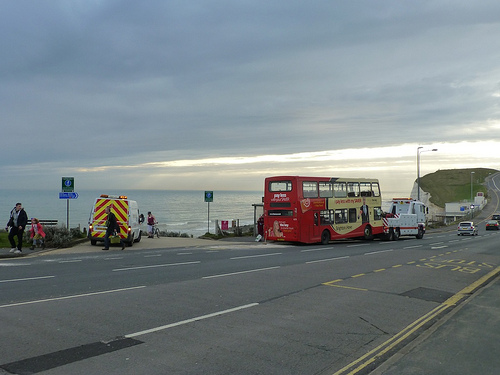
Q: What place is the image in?
A: It is at the road.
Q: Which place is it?
A: It is a road.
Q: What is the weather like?
A: It is cloudy.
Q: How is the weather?
A: It is cloudy.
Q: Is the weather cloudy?
A: Yes, it is cloudy.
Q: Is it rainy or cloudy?
A: It is cloudy.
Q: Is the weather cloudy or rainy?
A: It is cloudy.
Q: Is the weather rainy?
A: No, it is cloudy.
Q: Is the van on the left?
A: Yes, the van is on the left of the image.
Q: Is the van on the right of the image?
A: No, the van is on the left of the image.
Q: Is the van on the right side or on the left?
A: The van is on the left of the image.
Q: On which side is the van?
A: The van is on the left of the image.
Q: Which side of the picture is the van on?
A: The van is on the left of the image.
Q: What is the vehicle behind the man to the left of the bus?
A: The vehicle is a van.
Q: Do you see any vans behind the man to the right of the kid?
A: Yes, there is a van behind the man.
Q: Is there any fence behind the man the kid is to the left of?
A: No, there is a van behind the man.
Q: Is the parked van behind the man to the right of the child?
A: Yes, the van is behind the man.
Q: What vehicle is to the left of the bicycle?
A: The vehicle is a van.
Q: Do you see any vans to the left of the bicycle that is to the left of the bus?
A: Yes, there is a van to the left of the bicycle.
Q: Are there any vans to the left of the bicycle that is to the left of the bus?
A: Yes, there is a van to the left of the bicycle.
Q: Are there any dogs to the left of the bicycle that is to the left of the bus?
A: No, there is a van to the left of the bicycle.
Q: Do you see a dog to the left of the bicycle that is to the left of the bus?
A: No, there is a van to the left of the bicycle.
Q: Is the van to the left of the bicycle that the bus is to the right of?
A: Yes, the van is to the left of the bicycle.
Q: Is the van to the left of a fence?
A: No, the van is to the left of the bicycle.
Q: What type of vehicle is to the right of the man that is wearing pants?
A: The vehicle is a van.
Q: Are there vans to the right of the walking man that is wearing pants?
A: Yes, there is a van to the right of the man.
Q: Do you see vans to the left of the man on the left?
A: No, the van is to the right of the man.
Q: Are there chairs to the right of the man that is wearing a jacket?
A: No, there is a van to the right of the man.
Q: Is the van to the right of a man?
A: Yes, the van is to the right of a man.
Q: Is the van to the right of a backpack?
A: No, the van is to the right of a man.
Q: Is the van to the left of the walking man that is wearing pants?
A: No, the van is to the right of the man.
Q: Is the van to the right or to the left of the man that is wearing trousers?
A: The van is to the right of the man.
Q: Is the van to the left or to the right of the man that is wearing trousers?
A: The van is to the right of the man.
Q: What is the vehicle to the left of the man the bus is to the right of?
A: The vehicle is a van.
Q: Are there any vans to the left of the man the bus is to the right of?
A: Yes, there is a van to the left of the man.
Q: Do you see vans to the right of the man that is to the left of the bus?
A: No, the van is to the left of the man.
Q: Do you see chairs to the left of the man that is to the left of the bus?
A: No, there is a van to the left of the man.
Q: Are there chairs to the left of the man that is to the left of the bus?
A: No, there is a van to the left of the man.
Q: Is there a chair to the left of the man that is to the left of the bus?
A: No, there is a van to the left of the man.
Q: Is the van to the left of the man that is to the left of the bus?
A: Yes, the van is to the left of the man.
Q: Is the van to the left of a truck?
A: No, the van is to the left of the man.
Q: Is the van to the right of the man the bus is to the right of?
A: No, the van is to the left of the man.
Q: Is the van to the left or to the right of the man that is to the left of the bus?
A: The van is to the left of the man.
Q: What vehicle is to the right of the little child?
A: The vehicle is a van.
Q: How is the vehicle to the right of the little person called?
A: The vehicle is a van.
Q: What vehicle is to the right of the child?
A: The vehicle is a van.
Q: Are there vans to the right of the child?
A: Yes, there is a van to the right of the child.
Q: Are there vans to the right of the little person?
A: Yes, there is a van to the right of the child.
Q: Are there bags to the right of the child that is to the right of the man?
A: No, there is a van to the right of the child.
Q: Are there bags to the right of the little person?
A: No, there is a van to the right of the child.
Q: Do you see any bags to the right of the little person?
A: No, there is a van to the right of the child.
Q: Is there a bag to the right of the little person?
A: No, there is a van to the right of the child.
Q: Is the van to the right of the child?
A: Yes, the van is to the right of the child.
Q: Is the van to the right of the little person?
A: Yes, the van is to the right of the child.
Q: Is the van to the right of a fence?
A: No, the van is to the right of the child.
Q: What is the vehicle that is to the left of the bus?
A: The vehicle is a van.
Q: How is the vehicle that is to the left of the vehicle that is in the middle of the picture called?
A: The vehicle is a van.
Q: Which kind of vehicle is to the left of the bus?
A: The vehicle is a van.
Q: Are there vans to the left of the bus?
A: Yes, there is a van to the left of the bus.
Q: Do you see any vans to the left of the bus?
A: Yes, there is a van to the left of the bus.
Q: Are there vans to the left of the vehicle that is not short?
A: Yes, there is a van to the left of the bus.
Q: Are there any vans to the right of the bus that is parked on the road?
A: No, the van is to the left of the bus.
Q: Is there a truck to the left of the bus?
A: No, there is a van to the left of the bus.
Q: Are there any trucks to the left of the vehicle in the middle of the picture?
A: No, there is a van to the left of the bus.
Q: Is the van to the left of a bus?
A: Yes, the van is to the left of a bus.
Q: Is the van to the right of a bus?
A: No, the van is to the left of a bus.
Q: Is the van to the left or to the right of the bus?
A: The van is to the left of the bus.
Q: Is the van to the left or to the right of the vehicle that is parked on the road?
A: The van is to the left of the bus.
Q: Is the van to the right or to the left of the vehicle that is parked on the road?
A: The van is to the left of the bus.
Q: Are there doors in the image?
A: Yes, there are doors.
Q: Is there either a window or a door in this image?
A: Yes, there are doors.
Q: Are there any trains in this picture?
A: No, there are no trains.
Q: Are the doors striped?
A: Yes, the doors are striped.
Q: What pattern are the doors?
A: The doors are striped.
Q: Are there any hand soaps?
A: No, there are no hand soaps.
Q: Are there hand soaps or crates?
A: No, there are no hand soaps or crates.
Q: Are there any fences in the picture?
A: No, there are no fences.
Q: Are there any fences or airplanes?
A: No, there are no fences or airplanes.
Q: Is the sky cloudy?
A: Yes, the sky is cloudy.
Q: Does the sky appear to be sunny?
A: No, the sky is cloudy.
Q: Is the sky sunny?
A: No, the sky is cloudy.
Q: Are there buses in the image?
A: Yes, there is a bus.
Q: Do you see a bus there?
A: Yes, there is a bus.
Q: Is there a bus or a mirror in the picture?
A: Yes, there is a bus.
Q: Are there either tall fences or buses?
A: Yes, there is a tall bus.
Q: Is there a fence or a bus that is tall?
A: Yes, the bus is tall.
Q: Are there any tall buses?
A: Yes, there is a tall bus.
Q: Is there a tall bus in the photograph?
A: Yes, there is a tall bus.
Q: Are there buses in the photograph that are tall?
A: Yes, there is a bus that is tall.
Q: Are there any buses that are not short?
A: Yes, there is a tall bus.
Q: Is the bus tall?
A: Yes, the bus is tall.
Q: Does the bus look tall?
A: Yes, the bus is tall.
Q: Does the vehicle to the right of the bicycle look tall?
A: Yes, the bus is tall.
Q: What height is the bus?
A: The bus is tall.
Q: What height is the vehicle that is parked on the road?
A: The bus is tall.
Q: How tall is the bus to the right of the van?
A: The bus is tall.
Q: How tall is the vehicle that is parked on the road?
A: The bus is tall.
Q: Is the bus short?
A: No, the bus is tall.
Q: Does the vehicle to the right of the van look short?
A: No, the bus is tall.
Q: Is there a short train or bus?
A: No, there is a bus but it is tall.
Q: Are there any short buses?
A: No, there is a bus but it is tall.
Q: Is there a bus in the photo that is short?
A: No, there is a bus but it is tall.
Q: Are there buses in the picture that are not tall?
A: No, there is a bus but it is tall.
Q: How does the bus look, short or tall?
A: The bus is tall.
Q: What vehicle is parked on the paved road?
A: The vehicle is a bus.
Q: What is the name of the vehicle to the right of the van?
A: The vehicle is a bus.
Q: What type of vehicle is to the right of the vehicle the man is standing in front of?
A: The vehicle is a bus.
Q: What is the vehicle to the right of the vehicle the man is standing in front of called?
A: The vehicle is a bus.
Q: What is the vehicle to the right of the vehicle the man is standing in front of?
A: The vehicle is a bus.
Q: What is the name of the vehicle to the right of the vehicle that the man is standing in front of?
A: The vehicle is a bus.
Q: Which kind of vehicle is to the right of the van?
A: The vehicle is a bus.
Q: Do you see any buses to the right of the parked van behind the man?
A: Yes, there is a bus to the right of the van.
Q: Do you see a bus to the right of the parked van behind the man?
A: Yes, there is a bus to the right of the van.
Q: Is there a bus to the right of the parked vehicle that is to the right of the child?
A: Yes, there is a bus to the right of the van.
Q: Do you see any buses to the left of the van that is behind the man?
A: No, the bus is to the right of the van.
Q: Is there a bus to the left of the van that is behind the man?
A: No, the bus is to the right of the van.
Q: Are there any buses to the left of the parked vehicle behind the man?
A: No, the bus is to the right of the van.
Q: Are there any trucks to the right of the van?
A: No, there is a bus to the right of the van.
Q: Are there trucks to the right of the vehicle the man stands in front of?
A: No, there is a bus to the right of the van.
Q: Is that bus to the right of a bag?
A: No, the bus is to the right of a van.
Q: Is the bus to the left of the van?
A: No, the bus is to the right of the van.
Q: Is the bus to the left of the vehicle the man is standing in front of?
A: No, the bus is to the right of the van.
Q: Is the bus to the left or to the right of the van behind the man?
A: The bus is to the right of the van.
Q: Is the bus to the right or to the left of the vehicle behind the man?
A: The bus is to the right of the van.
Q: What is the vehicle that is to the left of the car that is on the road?
A: The vehicle is a bus.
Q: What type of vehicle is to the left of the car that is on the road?
A: The vehicle is a bus.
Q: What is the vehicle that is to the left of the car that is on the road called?
A: The vehicle is a bus.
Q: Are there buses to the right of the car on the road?
A: No, the bus is to the left of the car.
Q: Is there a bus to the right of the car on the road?
A: No, the bus is to the left of the car.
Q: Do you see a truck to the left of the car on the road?
A: No, there is a bus to the left of the car.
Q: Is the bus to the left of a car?
A: Yes, the bus is to the left of a car.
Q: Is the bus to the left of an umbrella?
A: No, the bus is to the left of a car.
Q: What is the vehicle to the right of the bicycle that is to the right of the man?
A: The vehicle is a bus.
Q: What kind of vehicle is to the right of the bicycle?
A: The vehicle is a bus.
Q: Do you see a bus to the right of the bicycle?
A: Yes, there is a bus to the right of the bicycle.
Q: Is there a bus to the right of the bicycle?
A: Yes, there is a bus to the right of the bicycle.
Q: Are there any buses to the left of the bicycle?
A: No, the bus is to the right of the bicycle.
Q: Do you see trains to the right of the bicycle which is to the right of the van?
A: No, there is a bus to the right of the bicycle.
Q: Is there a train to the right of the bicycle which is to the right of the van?
A: No, there is a bus to the right of the bicycle.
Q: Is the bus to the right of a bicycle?
A: Yes, the bus is to the right of a bicycle.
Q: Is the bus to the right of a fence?
A: No, the bus is to the right of a bicycle.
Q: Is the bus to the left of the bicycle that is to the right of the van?
A: No, the bus is to the right of the bicycle.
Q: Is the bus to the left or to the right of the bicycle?
A: The bus is to the right of the bicycle.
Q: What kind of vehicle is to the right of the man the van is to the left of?
A: The vehicle is a bus.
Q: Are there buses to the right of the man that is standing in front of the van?
A: Yes, there is a bus to the right of the man.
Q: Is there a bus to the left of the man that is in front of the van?
A: No, the bus is to the right of the man.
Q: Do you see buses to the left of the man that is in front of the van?
A: No, the bus is to the right of the man.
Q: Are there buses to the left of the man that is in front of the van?
A: No, the bus is to the right of the man.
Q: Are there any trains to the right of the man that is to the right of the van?
A: No, there is a bus to the right of the man.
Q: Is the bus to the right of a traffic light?
A: No, the bus is to the right of a man.